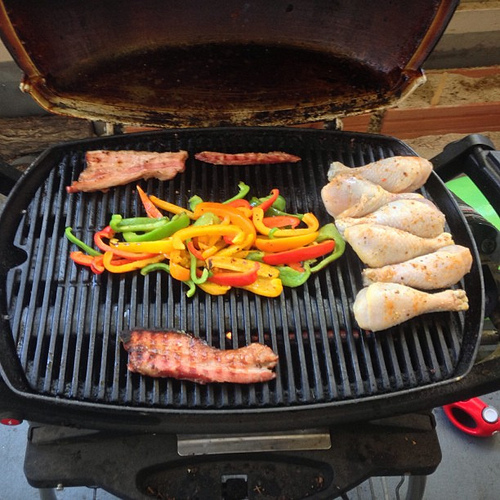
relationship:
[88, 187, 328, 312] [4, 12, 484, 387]
peppers cooking on grill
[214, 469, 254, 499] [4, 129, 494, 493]
knob on grill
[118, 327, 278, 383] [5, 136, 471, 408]
meat cooking on grill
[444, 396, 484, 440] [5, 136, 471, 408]
lighter for grill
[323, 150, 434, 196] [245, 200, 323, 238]
chicken beside pepper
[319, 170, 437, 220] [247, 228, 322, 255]
chicken beside pepper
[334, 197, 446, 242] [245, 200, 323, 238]
chicken beside pepper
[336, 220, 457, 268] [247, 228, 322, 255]
chicken beside pepper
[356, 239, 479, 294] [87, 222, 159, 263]
chicken beside pepper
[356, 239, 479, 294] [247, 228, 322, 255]
chicken beside pepper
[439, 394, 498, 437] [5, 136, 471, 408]
red item below grill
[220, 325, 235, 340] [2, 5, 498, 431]
flame beneath grill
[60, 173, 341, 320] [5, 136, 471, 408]
food on grill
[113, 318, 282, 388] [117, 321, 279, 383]
meat grilling ugrilling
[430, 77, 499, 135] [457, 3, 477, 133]
dirt on steps